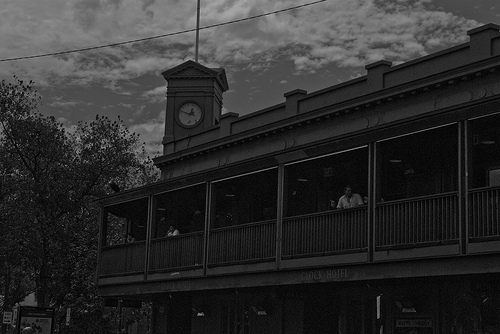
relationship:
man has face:
[335, 184, 364, 211] [344, 186, 353, 197]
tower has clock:
[159, 60, 230, 154] [175, 101, 205, 128]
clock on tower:
[175, 101, 205, 128] [159, 60, 230, 154]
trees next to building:
[2, 76, 157, 333] [93, 22, 500, 334]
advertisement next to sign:
[0, 309, 16, 327] [17, 303, 54, 333]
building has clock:
[93, 20, 499, 331] [175, 101, 205, 128]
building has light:
[93, 20, 499, 331] [195, 300, 211, 318]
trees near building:
[2, 76, 157, 333] [93, 20, 499, 331]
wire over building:
[2, 1, 334, 63] [93, 20, 499, 331]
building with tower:
[93, 20, 499, 331] [159, 60, 230, 154]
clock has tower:
[175, 101, 205, 128] [159, 60, 230, 154]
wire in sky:
[2, 1, 334, 63] [2, 1, 498, 188]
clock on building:
[175, 101, 205, 128] [93, 20, 499, 331]